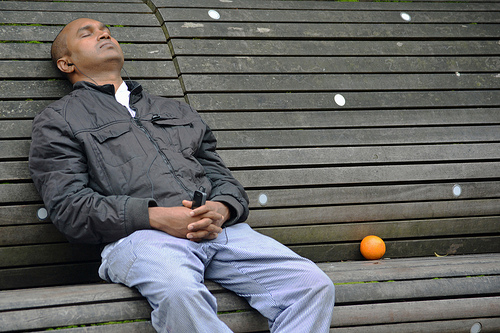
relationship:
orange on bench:
[355, 230, 391, 260] [1, 1, 497, 333]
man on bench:
[24, 2, 343, 332] [1, 1, 497, 333]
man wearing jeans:
[24, 2, 343, 332] [86, 209, 342, 332]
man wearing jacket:
[24, 2, 343, 332] [30, 79, 258, 235]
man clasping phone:
[24, 2, 343, 332] [187, 186, 207, 218]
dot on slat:
[333, 91, 350, 108] [187, 91, 500, 106]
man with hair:
[24, 2, 343, 332] [51, 27, 69, 58]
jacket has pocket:
[30, 79, 258, 235] [91, 120, 149, 168]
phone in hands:
[187, 186, 207, 218] [149, 198, 231, 242]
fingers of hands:
[178, 198, 227, 244] [149, 198, 231, 242]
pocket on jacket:
[91, 120, 149, 168] [30, 79, 258, 235]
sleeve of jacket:
[30, 104, 162, 248] [30, 79, 258, 235]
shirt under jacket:
[113, 78, 137, 120] [30, 79, 258, 235]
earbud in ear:
[67, 60, 75, 68] [54, 57, 75, 74]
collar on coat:
[68, 76, 145, 101] [30, 79, 258, 235]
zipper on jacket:
[132, 116, 195, 212] [30, 79, 258, 235]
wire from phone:
[66, 52, 207, 205] [187, 186, 207, 218]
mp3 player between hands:
[187, 186, 207, 218] [149, 198, 231, 242]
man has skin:
[24, 2, 343, 332] [45, 16, 131, 86]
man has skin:
[24, 2, 343, 332] [149, 198, 231, 242]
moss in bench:
[4, 36, 44, 45] [1, 1, 497, 333]